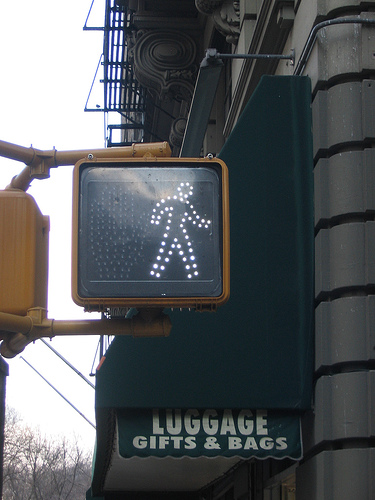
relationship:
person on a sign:
[146, 178, 214, 287] [68, 150, 234, 308]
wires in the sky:
[20, 336, 103, 434] [6, 17, 116, 463]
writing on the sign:
[132, 411, 288, 447] [112, 403, 302, 460]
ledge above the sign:
[85, 2, 196, 117] [92, 37, 301, 445]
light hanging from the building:
[177, 55, 228, 162] [219, 4, 362, 488]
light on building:
[177, 55, 228, 162] [230, 25, 373, 412]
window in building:
[253, 474, 298, 497] [105, 11, 373, 497]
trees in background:
[0, 410, 75, 498] [14, 346, 93, 471]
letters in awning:
[140, 404, 300, 461] [98, 74, 313, 496]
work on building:
[131, 25, 199, 93] [87, 2, 362, 496]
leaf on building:
[217, 7, 248, 24] [87, 2, 362, 496]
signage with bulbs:
[70, 155, 232, 308] [145, 183, 217, 281]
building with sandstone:
[105, 11, 373, 497] [127, 19, 236, 143]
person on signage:
[146, 178, 214, 287] [70, 155, 232, 308]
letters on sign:
[125, 406, 304, 454] [111, 413, 306, 458]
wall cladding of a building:
[340, 164, 363, 238] [286, 6, 363, 475]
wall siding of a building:
[340, 164, 363, 238] [286, 6, 363, 475]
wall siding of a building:
[312, 0, 374, 498] [302, 107, 363, 398]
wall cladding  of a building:
[312, 0, 374, 498] [302, 107, 363, 398]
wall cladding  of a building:
[312, 0, 374, 498] [290, 2, 352, 455]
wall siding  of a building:
[312, 0, 374, 498] [290, 2, 352, 455]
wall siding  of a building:
[312, 0, 374, 498] [322, 103, 358, 250]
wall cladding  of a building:
[312, 0, 374, 498] [322, 103, 358, 250]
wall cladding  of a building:
[312, 0, 374, 498] [83, 4, 361, 141]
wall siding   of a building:
[312, 0, 374, 498] [83, 4, 361, 141]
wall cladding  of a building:
[312, 0, 374, 498] [94, 18, 360, 150]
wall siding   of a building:
[312, 0, 374, 498] [94, 18, 360, 150]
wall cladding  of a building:
[312, 0, 374, 498] [118, 59, 363, 159]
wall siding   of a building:
[312, 0, 374, 498] [118, 59, 363, 159]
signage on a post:
[131, 182, 222, 274] [10, 130, 56, 321]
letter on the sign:
[147, 400, 163, 434] [111, 413, 306, 458]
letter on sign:
[162, 411, 187, 436] [117, 407, 312, 463]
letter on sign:
[184, 405, 204, 435] [117, 409, 310, 459]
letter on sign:
[198, 407, 225, 437] [112, 403, 302, 460]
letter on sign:
[216, 406, 239, 435] [115, 412, 310, 461]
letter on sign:
[237, 406, 258, 437] [117, 409, 310, 459]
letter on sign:
[253, 406, 271, 436] [117, 409, 310, 459]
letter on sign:
[222, 428, 247, 450] [117, 407, 312, 463]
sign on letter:
[117, 409, 310, 459] [239, 433, 260, 451]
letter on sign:
[258, 432, 273, 451] [117, 409, 310, 459]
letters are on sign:
[128, 408, 297, 451] [117, 407, 312, 463]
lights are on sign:
[79, 165, 221, 301] [68, 150, 234, 308]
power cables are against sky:
[15, 331, 98, 429] [0, 0, 122, 497]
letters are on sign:
[128, 408, 297, 451] [111, 413, 306, 458]